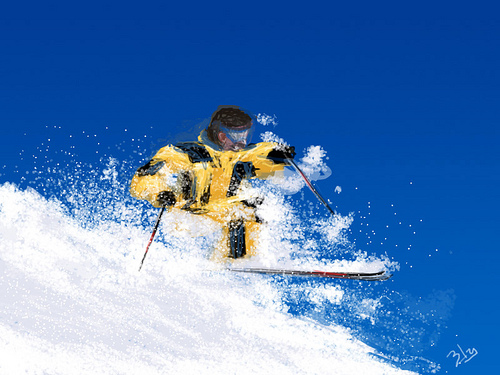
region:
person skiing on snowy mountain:
[110, 72, 406, 319]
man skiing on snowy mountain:
[110, 78, 445, 341]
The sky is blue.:
[333, 26, 443, 124]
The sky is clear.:
[358, 21, 452, 108]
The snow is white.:
[38, 300, 157, 367]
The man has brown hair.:
[204, 103, 253, 155]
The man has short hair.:
[202, 103, 258, 150]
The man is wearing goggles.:
[207, 102, 257, 155]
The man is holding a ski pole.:
[130, 177, 177, 283]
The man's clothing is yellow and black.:
[131, 103, 298, 267]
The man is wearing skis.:
[179, 249, 381, 287]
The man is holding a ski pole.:
[270, 135, 350, 225]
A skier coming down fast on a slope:
[105, 89, 399, 333]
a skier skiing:
[97, 108, 393, 290]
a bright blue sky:
[324, 0, 494, 103]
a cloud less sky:
[3, 0, 496, 92]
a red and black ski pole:
[133, 203, 164, 276]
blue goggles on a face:
[223, 127, 250, 143]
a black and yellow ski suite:
[136, 138, 292, 258]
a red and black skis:
[242, 261, 387, 278]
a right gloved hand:
[155, 192, 174, 210]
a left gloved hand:
[277, 143, 298, 167]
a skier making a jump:
[115, 97, 424, 303]